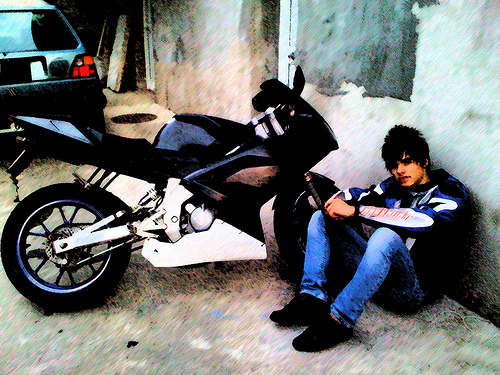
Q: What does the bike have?
A: Tire.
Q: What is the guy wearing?
A: Jeans.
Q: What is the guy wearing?
A: Jacket.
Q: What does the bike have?
A: Tire.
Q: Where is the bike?
A: Street.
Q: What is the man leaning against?
A: Building.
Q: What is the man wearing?
A: Jacket.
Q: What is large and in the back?
A: Tire.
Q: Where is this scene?
A: City corner.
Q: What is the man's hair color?
A: Black.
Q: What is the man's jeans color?
A: Blue.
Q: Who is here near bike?
A: Boy.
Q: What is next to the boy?
A: Motorcycle.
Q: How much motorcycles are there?
A: 1.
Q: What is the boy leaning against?
A: A wall.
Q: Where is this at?
A: Alleyway.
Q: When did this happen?
A: During the day time.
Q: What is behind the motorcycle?
A: A car.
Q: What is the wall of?
A: A building.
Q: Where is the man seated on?
A: On the ground.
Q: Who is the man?
A: A motorcyclist.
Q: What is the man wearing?
A: Blue jeans.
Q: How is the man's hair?
A: Sticking up.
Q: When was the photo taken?
A: Daytime.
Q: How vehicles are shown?
A: Two.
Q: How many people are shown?
A: One.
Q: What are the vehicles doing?
A: Parked.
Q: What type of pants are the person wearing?
A: Jeans.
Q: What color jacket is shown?
A: Black, white, and blue.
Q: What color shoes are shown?
A: Black.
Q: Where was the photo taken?
A: On the street.